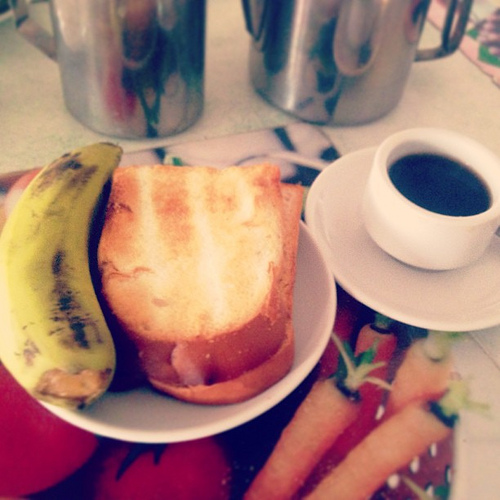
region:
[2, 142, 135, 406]
yellow banana on white bowl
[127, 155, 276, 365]
piece of toast on bowl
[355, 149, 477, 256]
white cup of black coffee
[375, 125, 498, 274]
coffee cup on saucer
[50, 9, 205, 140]
metal pot in background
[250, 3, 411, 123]
metal pot in background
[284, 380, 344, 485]
orange carrot on mat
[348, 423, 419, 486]
orange carrot on mat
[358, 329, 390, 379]
orange carrot on mat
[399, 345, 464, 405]
orange carrot on mat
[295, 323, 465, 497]
bunch of four carrots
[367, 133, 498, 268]
small cup of black coffee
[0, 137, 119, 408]
a banana with it's stem removed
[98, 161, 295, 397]
half a toasted white bread sandwich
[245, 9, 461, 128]
silver carafe used for coffee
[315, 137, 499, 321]
white ceramic cup and saucer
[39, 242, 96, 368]
large bruised area of a banana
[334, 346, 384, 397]
green leafy top of a carrot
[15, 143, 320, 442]
small plate containg a sandwich and banana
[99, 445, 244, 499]
red tomato that decorates a place mat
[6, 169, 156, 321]
this is a banana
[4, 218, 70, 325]
the banana is yellow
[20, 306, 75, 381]
this is the skin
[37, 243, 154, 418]
the banana is dirty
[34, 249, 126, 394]
this is a black spot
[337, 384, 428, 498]
these are carrots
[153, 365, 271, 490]
this is a plate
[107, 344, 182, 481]
the plate is white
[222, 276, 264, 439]
these are two pieces of toast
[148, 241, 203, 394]
the bread is toasted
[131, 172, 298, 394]
Bread on the plate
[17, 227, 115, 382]
A banana in the photo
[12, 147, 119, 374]
A banana skin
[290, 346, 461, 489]
Carrots on the plate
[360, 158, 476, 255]
A cup on the table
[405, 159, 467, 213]
Coffee on the plate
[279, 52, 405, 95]
Cup on the table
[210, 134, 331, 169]
A table in the picture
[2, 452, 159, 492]
Tomatoes in the photo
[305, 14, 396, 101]
Metallic cup on the table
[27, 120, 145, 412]
the banana on the plate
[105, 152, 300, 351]
the toast on the plate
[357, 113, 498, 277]
the cup of espresso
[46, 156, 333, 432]
the plate is white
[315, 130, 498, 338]
the plate under the cup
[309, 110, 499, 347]
the plate is white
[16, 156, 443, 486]
the place mat under the plate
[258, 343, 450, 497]
carrots on the place mat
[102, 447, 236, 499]
the tomato on the place mat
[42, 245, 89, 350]
black spots on the banana